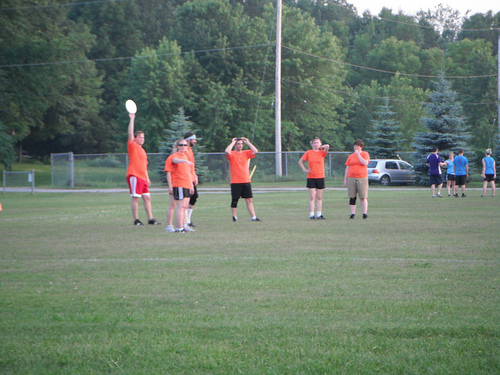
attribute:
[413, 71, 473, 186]
pine tree — blue-green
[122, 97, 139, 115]
frisbee — small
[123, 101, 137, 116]
frisbee — yellow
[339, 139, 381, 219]
player — woman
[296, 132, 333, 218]
player — woman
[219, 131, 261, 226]
player — woman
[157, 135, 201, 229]
player — woman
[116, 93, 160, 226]
player — woman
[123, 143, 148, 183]
shirt — bright orange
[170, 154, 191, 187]
shirt — bright orange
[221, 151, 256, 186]
shirt — bright orange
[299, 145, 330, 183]
shirt — bright orange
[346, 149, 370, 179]
shirt — bright orange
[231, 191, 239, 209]
brace — black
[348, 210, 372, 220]
shoe — black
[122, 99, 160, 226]
short — red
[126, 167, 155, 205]
shorts — red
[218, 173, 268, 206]
shorts — black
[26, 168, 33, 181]
sign — white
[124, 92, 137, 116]
frisbee — small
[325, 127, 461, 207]
car — silver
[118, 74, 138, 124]
frisbee — small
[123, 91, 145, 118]
frisbee — small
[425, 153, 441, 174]
shirt — dark blue